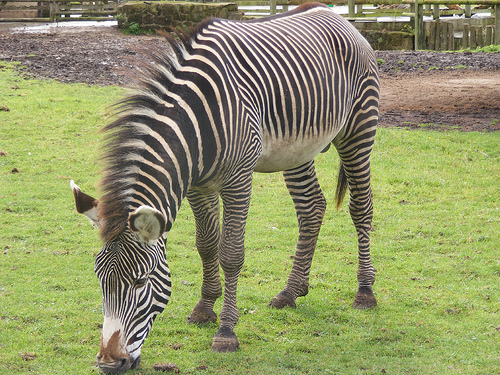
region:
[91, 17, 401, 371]
the zebra is standing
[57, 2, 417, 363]
the zebra is eating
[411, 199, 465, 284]
the grass is green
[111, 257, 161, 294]
the eye is black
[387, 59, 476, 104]
the dirt is brown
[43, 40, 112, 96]
the rocks are black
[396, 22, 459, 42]
the fence is wooden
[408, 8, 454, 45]
the fence is brown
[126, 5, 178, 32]
the bushes are green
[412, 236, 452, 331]
the grass is short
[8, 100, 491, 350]
grass is lush and green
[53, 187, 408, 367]
grass is lush and green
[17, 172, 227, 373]
The zebra is eating grass.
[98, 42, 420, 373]
This zebra has stripes.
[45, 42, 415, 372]
The zebra has four legs.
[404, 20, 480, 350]
The grass is really green.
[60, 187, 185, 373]
The zebra has large ears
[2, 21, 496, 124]
There is rocky dirt in the back of the landscape.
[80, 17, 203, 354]
The zebra has a mane.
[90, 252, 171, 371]
The zebra has brown on its nose.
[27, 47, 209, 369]
The zebra is very hungry.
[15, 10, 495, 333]
The zebra is in great shape.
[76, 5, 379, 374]
this is a zebra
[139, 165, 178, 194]
the fur is white and black in color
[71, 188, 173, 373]
the zebra is feeding on grass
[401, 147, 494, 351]
this is the grass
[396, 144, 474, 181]
the grass is green in color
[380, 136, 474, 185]
the grass is long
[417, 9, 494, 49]
this is a fence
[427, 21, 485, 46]
the fence is wooden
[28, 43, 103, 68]
the ground is dirty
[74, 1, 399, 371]
A black and white zebra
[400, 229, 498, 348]
Green grass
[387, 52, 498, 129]
Muddy brown dirt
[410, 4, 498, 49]
Brown log fence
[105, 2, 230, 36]
A stone and mortar fence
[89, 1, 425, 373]
Full grown zebra eating grass in a field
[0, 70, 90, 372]
An unwell kept lawn for feeding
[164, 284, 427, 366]
Hooves of an adult zebra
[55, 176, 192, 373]
The face of an adult zebra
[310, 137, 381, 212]
The tail of an adult zebra